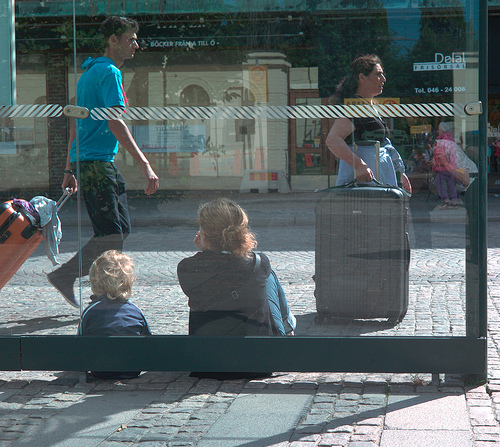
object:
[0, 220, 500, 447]
street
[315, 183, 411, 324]
suitcase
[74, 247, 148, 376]
child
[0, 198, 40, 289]
luggage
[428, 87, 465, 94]
number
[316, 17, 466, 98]
window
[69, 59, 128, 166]
shirt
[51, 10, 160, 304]
man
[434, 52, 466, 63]
name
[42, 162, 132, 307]
pants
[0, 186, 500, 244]
pavement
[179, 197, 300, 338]
woman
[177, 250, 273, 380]
jacket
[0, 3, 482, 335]
glass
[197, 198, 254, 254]
hair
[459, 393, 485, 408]
edge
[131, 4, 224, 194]
shade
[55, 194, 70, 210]
handle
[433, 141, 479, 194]
bag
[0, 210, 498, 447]
ground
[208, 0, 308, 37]
partition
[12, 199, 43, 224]
clothes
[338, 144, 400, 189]
skirt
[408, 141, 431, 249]
person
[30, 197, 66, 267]
sweaters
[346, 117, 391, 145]
top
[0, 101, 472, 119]
stripe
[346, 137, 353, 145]
back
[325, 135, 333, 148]
elbow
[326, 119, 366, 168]
arm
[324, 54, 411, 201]
woman